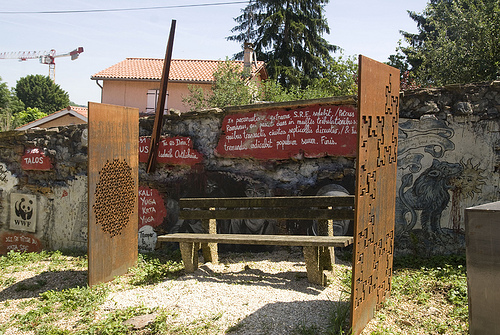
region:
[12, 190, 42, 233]
panda is on sign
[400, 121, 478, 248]
painting is on wall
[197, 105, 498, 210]
the wall is stone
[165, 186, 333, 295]
the bench in sand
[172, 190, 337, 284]
the bench is stone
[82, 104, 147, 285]
the planks are iron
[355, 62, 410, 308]
designs on the plank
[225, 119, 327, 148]
the writing is white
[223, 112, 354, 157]
writing on red sign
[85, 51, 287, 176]
buildings behind the wall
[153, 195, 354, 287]
brown bench on ground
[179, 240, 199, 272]
bench has concrete legs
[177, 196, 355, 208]
wooden slats on bench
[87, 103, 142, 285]
metal wall to the left of bench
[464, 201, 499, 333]
metal box to the right of bench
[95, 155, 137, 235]
round design on copper wall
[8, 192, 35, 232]
black and white panda on poster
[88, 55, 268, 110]
pink building behind stone wall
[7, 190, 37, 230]
poster on wall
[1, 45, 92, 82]
crane against sky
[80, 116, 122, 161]
part of a board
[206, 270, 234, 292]
part of a floor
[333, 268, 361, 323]
edge of a board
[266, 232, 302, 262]
edge of a bench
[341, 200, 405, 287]
part of a surface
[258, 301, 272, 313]
edge of a shade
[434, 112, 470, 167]
part of a fence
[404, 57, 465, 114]
edge of a fence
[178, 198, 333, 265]
this is a bench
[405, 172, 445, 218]
this is a lion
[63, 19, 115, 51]
this is the sky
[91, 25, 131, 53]
the sky is blue in color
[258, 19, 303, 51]
this is a tree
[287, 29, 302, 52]
the tree has green leaves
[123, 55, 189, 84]
this is the roof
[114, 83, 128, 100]
this is the wall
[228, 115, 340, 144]
this is a writing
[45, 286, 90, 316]
the grass is green in color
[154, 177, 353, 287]
One wooden bench.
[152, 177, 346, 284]
Nobody on the bench.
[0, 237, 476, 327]
The grass is green.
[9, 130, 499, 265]
Stone wall behind the bench.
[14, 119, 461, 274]
Paintings on the wall.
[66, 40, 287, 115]
House behind the wall.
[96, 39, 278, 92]
Clay tile on the roof.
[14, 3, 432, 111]
Sunny day with clouds.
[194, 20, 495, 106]
Green trees behind the wall.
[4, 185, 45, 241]
WWF poster on the wall